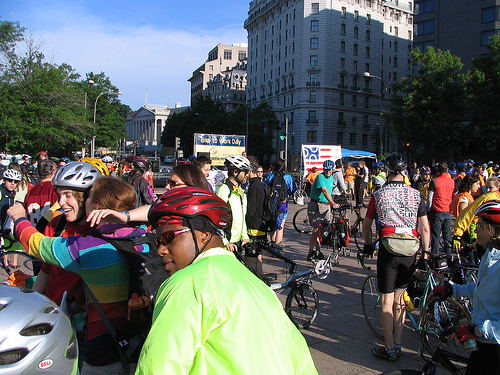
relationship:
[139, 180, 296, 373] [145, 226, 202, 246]
man wearing goggles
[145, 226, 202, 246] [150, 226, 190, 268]
goggles on top of face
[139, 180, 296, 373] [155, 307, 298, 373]
man wearing jacket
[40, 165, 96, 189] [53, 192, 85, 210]
helmet on top of head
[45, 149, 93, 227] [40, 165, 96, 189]
woman wearing helmet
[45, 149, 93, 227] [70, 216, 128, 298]
woman wearing jacket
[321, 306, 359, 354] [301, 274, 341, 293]
shadow on top of ground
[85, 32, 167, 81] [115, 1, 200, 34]
clouds in sky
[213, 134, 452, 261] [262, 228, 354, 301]
people on top of street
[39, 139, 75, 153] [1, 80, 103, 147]
leaves attached to trees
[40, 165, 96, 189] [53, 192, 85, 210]
helmet on head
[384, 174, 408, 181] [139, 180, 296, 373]
skin of man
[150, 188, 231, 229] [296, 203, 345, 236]
helmet for bike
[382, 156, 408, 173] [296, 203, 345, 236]
helmet for bike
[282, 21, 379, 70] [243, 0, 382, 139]
windows attached to building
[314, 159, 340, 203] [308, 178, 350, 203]
man wearing shirt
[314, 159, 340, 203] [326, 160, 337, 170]
man wearing helmet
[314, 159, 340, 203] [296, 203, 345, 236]
man pushing bike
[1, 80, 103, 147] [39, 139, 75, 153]
trees with leaves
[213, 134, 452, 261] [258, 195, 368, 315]
people with bikes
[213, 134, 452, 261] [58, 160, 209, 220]
people with helmets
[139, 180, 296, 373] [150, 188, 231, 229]
man wearing helmet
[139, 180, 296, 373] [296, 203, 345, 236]
man with bike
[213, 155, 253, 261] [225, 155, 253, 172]
people wearing helmet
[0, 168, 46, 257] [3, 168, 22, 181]
person wearing helmet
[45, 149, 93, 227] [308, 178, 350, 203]
woman wearing shirt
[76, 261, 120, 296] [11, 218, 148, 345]
stripes on top of jacket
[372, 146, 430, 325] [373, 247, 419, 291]
man wearing shorts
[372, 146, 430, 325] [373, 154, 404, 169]
man wearing helmet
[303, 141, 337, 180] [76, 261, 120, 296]
sign with stripes